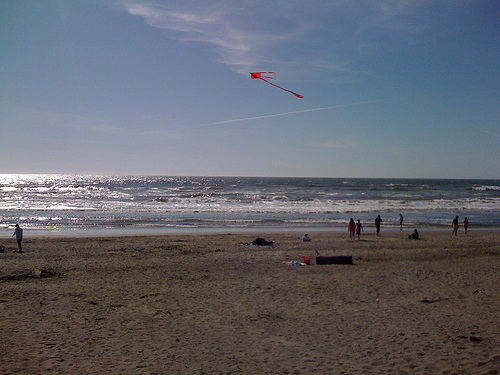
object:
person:
[11, 224, 22, 253]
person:
[348, 218, 357, 241]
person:
[451, 215, 459, 235]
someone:
[302, 233, 310, 242]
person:
[354, 219, 363, 240]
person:
[375, 214, 382, 236]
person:
[399, 214, 404, 231]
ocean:
[0, 173, 500, 237]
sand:
[110, 263, 497, 373]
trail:
[195, 99, 387, 127]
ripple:
[86, 214, 112, 223]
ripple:
[179, 214, 203, 221]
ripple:
[37, 182, 380, 216]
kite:
[248, 71, 304, 99]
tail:
[260, 76, 304, 98]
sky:
[0, 0, 499, 180]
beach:
[0, 230, 500, 375]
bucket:
[302, 255, 310, 264]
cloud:
[125, 4, 424, 82]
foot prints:
[30, 290, 472, 366]